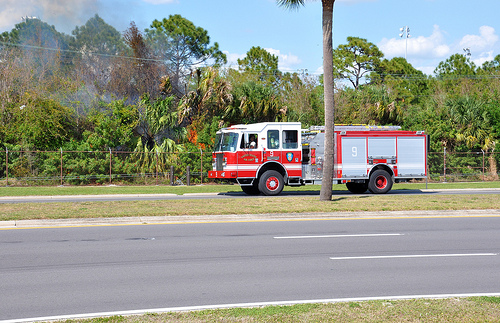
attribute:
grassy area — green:
[2, 194, 496, 223]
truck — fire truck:
[203, 114, 432, 201]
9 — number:
[264, 148, 277, 158]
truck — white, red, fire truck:
[217, 104, 430, 207]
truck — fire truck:
[226, 119, 435, 196]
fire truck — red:
[201, 118, 433, 198]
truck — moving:
[202, 118, 433, 195]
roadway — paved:
[0, 218, 499, 298]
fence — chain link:
[9, 136, 495, 191]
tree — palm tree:
[316, 7, 338, 200]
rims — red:
[252, 166, 310, 198]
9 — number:
[349, 145, 359, 158]